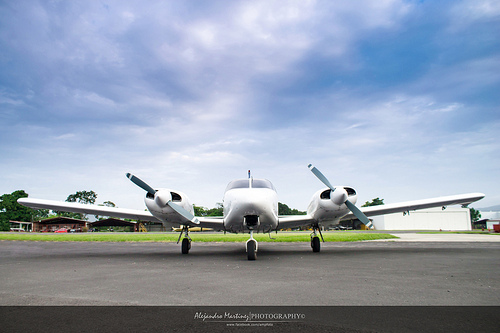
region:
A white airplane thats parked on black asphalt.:
[16, 158, 486, 265]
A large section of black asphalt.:
[1, 240, 498, 304]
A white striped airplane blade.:
[118, 160, 206, 242]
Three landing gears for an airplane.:
[166, 224, 359, 280]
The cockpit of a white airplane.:
[216, 165, 289, 258]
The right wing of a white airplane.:
[11, 183, 227, 255]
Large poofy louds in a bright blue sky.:
[13, 10, 491, 169]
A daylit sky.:
[1, 2, 496, 166]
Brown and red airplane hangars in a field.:
[7, 212, 163, 254]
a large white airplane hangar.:
[360, 198, 478, 240]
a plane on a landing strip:
[12, 155, 493, 267]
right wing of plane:
[367, 190, 489, 212]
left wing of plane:
[6, 186, 142, 231]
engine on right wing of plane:
[294, 157, 376, 234]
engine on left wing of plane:
[113, 165, 208, 242]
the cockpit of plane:
[217, 165, 281, 222]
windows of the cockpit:
[219, 163, 281, 196]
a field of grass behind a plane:
[7, 201, 397, 293]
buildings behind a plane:
[3, 180, 176, 239]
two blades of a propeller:
[301, 157, 380, 238]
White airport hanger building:
[361, 195, 478, 232]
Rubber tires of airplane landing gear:
[172, 236, 336, 257]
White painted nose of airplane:
[220, 188, 284, 232]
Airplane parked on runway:
[17, 169, 488, 262]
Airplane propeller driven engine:
[302, 160, 376, 233]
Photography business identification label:
[188, 308, 313, 330]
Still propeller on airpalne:
[120, 168, 200, 225]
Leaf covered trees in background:
[5, 187, 120, 234]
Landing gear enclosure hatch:
[173, 223, 186, 247]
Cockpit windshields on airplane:
[222, 176, 276, 194]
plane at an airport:
[12, 156, 484, 271]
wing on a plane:
[363, 188, 488, 213]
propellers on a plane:
[303, 161, 375, 228]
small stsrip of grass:
[3, 228, 401, 240]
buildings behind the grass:
[1, 217, 156, 234]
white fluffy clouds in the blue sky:
[136, 4, 490, 193]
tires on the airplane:
[177, 235, 330, 260]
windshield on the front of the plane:
[223, 175, 273, 189]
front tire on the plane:
[239, 236, 264, 260]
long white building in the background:
[367, 203, 473, 231]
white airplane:
[5, 142, 480, 252]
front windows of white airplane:
[225, 180, 272, 195]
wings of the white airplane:
[12, 181, 489, 257]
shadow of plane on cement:
[13, 229, 493, 259]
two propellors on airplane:
[120, 160, 377, 235]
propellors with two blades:
[123, 158, 373, 225]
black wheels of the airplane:
[169, 231, 326, 260]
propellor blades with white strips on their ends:
[120, 164, 377, 232]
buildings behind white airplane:
[0, 196, 477, 233]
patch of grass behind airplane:
[3, 226, 399, 247]